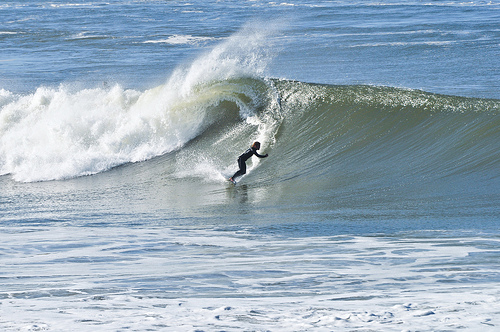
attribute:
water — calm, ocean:
[0, 0, 497, 326]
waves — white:
[4, 73, 497, 207]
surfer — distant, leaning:
[227, 139, 269, 182]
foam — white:
[1, 55, 248, 185]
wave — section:
[196, 51, 490, 149]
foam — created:
[1, 24, 316, 186]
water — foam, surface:
[125, 229, 371, 310]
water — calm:
[0, 1, 500, 93]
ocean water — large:
[0, 0, 499, 331]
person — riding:
[230, 139, 272, 181]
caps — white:
[10, 23, 200, 51]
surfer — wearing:
[228, 144, 268, 180]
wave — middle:
[0, 14, 497, 188]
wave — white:
[0, 24, 500, 214]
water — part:
[117, 209, 443, 316]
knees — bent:
[234, 160, 249, 178]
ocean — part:
[49, 20, 172, 158]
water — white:
[21, 22, 153, 152]